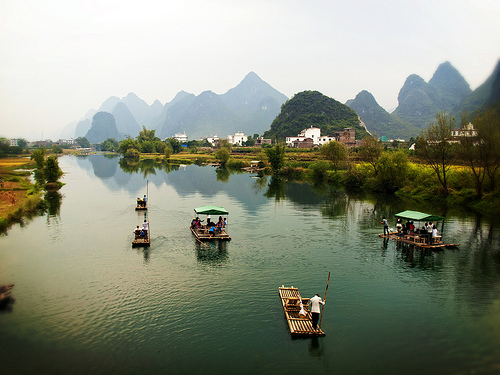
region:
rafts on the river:
[110, 173, 450, 336]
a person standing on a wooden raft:
[305, 266, 330, 336]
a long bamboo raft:
[275, 275, 325, 337]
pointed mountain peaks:
[95, 72, 270, 124]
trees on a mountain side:
[400, 80, 430, 120]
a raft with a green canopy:
[385, 202, 450, 252]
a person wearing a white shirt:
[306, 290, 322, 310]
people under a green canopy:
[190, 205, 235, 235]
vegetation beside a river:
[20, 150, 67, 215]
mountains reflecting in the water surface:
[91, 170, 262, 210]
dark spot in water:
[38, 324, 60, 344]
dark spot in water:
[96, 308, 119, 345]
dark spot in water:
[166, 336, 183, 363]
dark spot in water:
[223, 326, 251, 351]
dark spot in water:
[224, 286, 252, 315]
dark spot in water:
[365, 278, 400, 310]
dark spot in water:
[355, 250, 382, 280]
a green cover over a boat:
[193, 204, 230, 217]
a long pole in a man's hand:
[314, 266, 334, 330]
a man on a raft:
[305, 289, 324, 329]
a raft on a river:
[276, 280, 326, 338]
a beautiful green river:
[1, 145, 498, 372]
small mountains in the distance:
[79, 58, 471, 150]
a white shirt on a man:
[306, 295, 325, 313]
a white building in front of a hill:
[285, 124, 333, 149]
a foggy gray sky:
[0, 1, 497, 138]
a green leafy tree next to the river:
[42, 154, 63, 183]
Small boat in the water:
[274, 258, 340, 358]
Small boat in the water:
[373, 187, 453, 272]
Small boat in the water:
[130, 173, 161, 215]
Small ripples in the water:
[29, 250, 66, 311]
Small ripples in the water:
[138, 291, 185, 348]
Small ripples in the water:
[339, 296, 388, 342]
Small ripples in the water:
[285, 227, 321, 264]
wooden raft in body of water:
[265, 263, 337, 345]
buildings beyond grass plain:
[282, 118, 364, 155]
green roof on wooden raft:
[185, 197, 232, 223]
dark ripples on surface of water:
[117, 299, 186, 342]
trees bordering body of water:
[408, 107, 492, 202]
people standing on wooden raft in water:
[371, 197, 473, 257]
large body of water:
[1, 148, 498, 370]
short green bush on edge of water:
[121, 145, 143, 162]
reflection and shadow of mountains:
[52, 85, 165, 147]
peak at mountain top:
[236, 68, 267, 85]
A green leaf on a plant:
[315, 106, 320, 111]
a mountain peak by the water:
[82, 115, 132, 142]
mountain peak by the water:
[101, 95, 148, 141]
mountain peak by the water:
[125, 93, 155, 128]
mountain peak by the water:
[163, 89, 195, 142]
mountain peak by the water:
[222, 72, 279, 125]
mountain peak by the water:
[349, 88, 398, 139]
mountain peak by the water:
[393, 93, 443, 143]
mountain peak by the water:
[400, 73, 431, 102]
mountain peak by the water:
[426, 58, 472, 105]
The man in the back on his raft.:
[272, 270, 336, 349]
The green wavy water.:
[66, 273, 198, 340]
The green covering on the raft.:
[191, 203, 226, 220]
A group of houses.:
[283, 124, 345, 150]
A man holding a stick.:
[311, 274, 331, 334]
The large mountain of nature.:
[266, 82, 351, 145]